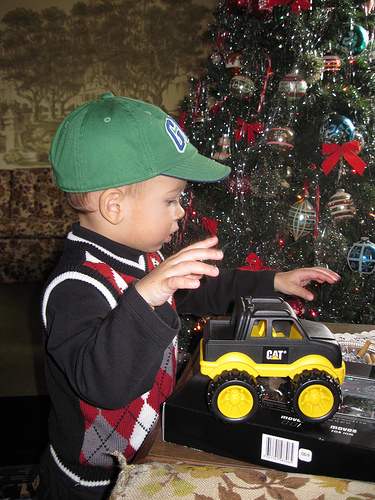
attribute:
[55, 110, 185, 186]
cap — green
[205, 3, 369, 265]
christmas tree — decorated, inside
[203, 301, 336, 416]
toy truck — black, yellow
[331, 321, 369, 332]
table — wooden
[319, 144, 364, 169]
bow — red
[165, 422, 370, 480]
box — black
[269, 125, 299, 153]
ornament — bright